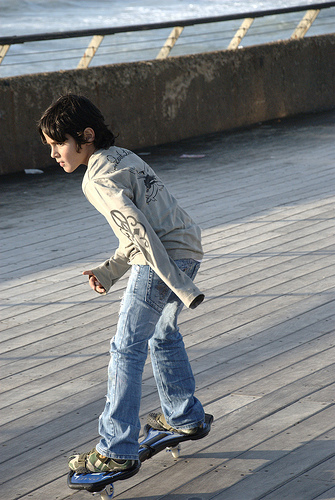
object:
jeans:
[95, 258, 205, 460]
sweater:
[82, 146, 205, 310]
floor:
[3, 110, 335, 498]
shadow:
[126, 436, 335, 500]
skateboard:
[66, 415, 215, 499]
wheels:
[100, 485, 117, 500]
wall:
[0, 33, 334, 175]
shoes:
[66, 445, 138, 475]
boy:
[38, 93, 207, 474]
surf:
[0, 4, 334, 79]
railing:
[0, 1, 334, 76]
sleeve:
[80, 173, 205, 310]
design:
[107, 209, 149, 265]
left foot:
[67, 442, 140, 473]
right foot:
[145, 402, 209, 438]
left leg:
[95, 264, 171, 457]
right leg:
[151, 257, 204, 418]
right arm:
[105, 248, 132, 286]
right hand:
[81, 267, 113, 295]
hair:
[38, 92, 119, 153]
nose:
[51, 150, 60, 159]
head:
[36, 95, 118, 174]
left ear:
[84, 128, 95, 143]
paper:
[24, 168, 44, 175]